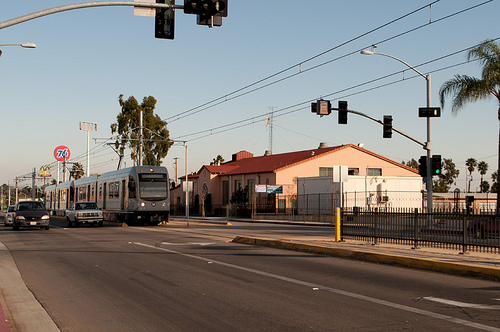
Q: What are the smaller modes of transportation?
A: Cars.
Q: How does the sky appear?
A: Blue and clear.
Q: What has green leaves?
A: The trees.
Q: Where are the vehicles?
A: On the road.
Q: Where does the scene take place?
A: Near a city street.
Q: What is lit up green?
A: Traffic light.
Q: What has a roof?
A: A building.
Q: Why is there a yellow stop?
A: Trolley stop.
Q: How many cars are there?
A: Three.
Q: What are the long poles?
A: Lights.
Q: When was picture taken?
A: Daytime.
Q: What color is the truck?
A: White.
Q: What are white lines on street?
A: Lanes.